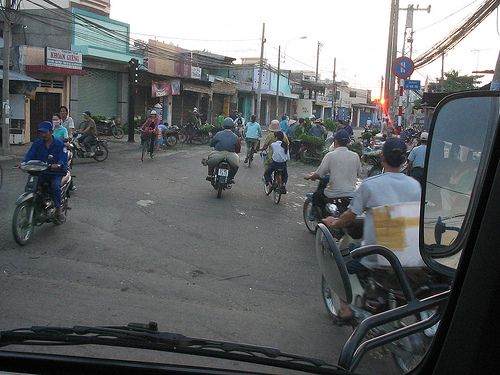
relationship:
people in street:
[17, 95, 443, 285] [8, 118, 402, 375]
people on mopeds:
[17, 95, 443, 285] [26, 144, 427, 317]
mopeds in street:
[26, 144, 427, 317] [8, 118, 402, 375]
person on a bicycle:
[261, 120, 287, 164] [260, 150, 282, 201]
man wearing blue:
[22, 126, 71, 218] [28, 141, 69, 197]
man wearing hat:
[22, 126, 71, 218] [38, 120, 55, 133]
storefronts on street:
[4, 3, 367, 130] [8, 118, 402, 375]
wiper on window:
[11, 315, 305, 366] [1, 5, 465, 374]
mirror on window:
[427, 99, 478, 266] [1, 5, 465, 374]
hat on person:
[268, 120, 281, 131] [261, 120, 287, 164]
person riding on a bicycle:
[261, 120, 287, 164] [260, 150, 282, 201]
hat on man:
[38, 120, 55, 133] [22, 126, 71, 218]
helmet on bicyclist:
[225, 118, 235, 128] [202, 124, 242, 158]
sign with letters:
[45, 47, 83, 74] [51, 48, 82, 70]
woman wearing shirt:
[140, 114, 162, 147] [145, 119, 157, 132]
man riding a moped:
[22, 126, 71, 218] [15, 153, 70, 234]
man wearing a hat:
[22, 126, 71, 218] [38, 120, 55, 133]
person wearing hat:
[261, 120, 287, 164] [268, 120, 281, 131]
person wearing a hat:
[261, 120, 287, 164] [268, 120, 281, 131]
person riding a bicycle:
[261, 120, 287, 164] [260, 150, 282, 201]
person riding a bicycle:
[267, 136, 287, 190] [260, 150, 282, 201]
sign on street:
[391, 55, 411, 75] [8, 118, 402, 375]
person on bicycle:
[267, 136, 287, 190] [260, 150, 282, 201]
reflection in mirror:
[429, 111, 476, 249] [427, 99, 478, 266]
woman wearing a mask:
[52, 116, 69, 147] [53, 118, 60, 127]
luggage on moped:
[205, 146, 240, 165] [199, 138, 246, 197]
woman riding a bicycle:
[140, 114, 162, 147] [138, 134, 158, 160]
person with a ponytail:
[267, 136, 287, 190] [279, 137, 290, 152]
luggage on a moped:
[205, 146, 240, 165] [199, 138, 246, 197]